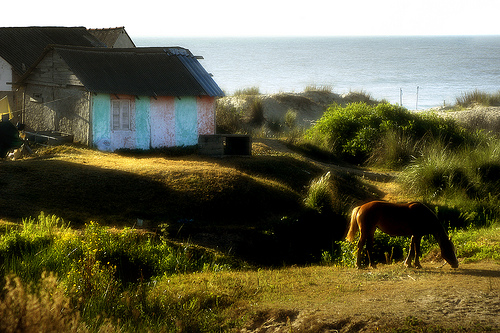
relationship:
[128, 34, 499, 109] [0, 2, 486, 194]
water in background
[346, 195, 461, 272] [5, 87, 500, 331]
horse in field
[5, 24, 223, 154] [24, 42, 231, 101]
house has roof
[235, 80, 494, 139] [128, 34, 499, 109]
sand dune near ocean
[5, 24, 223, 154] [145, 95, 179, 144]
house has stripe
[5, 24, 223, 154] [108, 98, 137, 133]
house has window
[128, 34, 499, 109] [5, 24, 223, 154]
water behind house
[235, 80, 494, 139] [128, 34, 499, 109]
sand dune by water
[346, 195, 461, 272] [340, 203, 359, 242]
horse has tail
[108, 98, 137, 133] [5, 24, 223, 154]
window on house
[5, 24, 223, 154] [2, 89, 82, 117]
house has wire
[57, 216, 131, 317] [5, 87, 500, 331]
flowers on field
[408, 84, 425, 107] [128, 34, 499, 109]
pole near water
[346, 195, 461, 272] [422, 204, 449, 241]
horse has mane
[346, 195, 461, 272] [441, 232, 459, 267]
horse has head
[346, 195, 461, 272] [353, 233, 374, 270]
horse has leg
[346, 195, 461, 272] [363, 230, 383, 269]
horse has leg